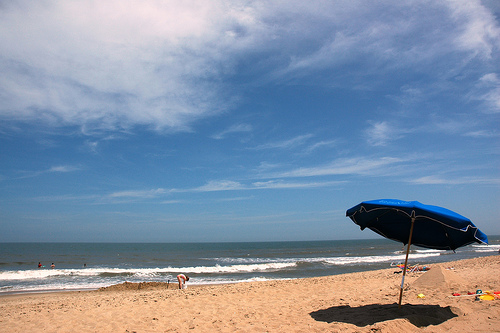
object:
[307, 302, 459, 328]
shadow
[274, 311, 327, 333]
sand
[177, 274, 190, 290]
person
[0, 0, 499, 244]
sky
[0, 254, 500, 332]
beach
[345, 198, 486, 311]
umbrella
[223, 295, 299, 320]
sand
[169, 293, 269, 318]
sand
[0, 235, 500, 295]
water